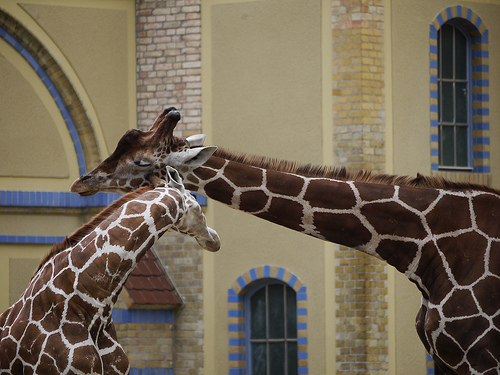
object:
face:
[69, 127, 156, 196]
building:
[2, 1, 498, 371]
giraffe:
[69, 106, 500, 374]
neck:
[30, 188, 180, 314]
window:
[242, 282, 298, 375]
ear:
[174, 146, 219, 169]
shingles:
[123, 247, 184, 306]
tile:
[129, 288, 183, 306]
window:
[434, 20, 476, 169]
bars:
[249, 283, 296, 374]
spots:
[353, 198, 433, 246]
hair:
[214, 146, 500, 195]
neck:
[205, 145, 436, 270]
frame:
[245, 284, 296, 375]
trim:
[226, 265, 309, 374]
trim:
[428, 4, 491, 174]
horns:
[150, 110, 181, 141]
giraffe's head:
[68, 106, 219, 197]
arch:
[0, 0, 107, 178]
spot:
[435, 229, 492, 290]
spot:
[420, 191, 475, 236]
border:
[217, 264, 313, 373]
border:
[427, 5, 491, 173]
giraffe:
[0, 165, 221, 375]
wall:
[1, 6, 499, 369]